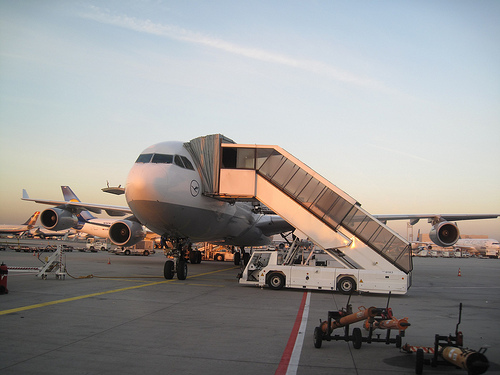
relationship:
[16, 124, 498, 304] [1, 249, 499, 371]
plane on runway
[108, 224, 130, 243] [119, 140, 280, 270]
engine on plane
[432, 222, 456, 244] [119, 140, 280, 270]
engine on plane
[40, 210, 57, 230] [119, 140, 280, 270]
engine on plane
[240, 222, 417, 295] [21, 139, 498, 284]
vehicle next to plane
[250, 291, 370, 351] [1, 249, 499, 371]
stripe on runway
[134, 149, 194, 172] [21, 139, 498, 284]
window on plane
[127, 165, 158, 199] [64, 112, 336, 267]
nose of plane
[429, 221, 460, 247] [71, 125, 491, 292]
engine on plane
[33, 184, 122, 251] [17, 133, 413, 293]
wing of plane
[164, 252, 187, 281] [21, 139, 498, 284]
wheels of plane